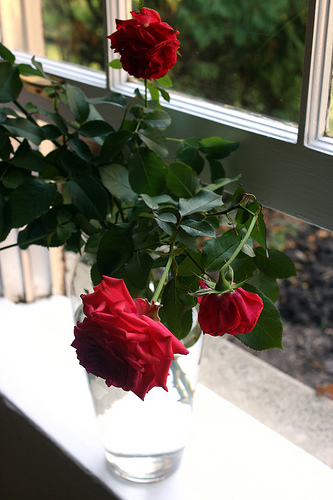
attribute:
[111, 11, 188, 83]
rose — open, red, small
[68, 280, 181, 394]
rose — open, red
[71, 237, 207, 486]
vase — clear, glass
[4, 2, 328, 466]
window — opened, open, white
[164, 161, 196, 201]
rose leaf — green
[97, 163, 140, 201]
rose leaf — green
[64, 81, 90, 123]
rose leaf — green, curled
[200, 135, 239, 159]
rose leaf — green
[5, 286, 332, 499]
window sill — white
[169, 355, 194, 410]
rose stem — green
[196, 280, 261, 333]
rose — drooping, pointing down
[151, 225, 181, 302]
stem — thorny, green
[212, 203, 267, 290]
stem — green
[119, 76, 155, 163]
stem — green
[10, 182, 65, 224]
rose leaf — green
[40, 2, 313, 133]
bush — leafy, green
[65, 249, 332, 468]
sidewalk — grey